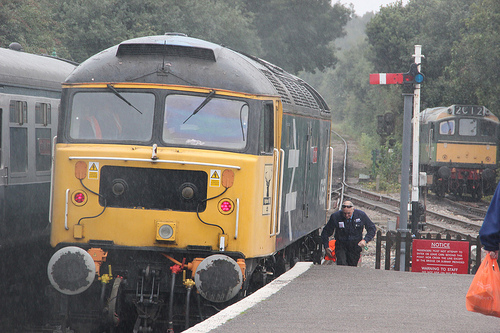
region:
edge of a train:
[259, 169, 271, 220]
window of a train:
[192, 120, 202, 133]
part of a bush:
[454, 51, 459, 62]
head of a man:
[343, 193, 351, 213]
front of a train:
[117, 250, 139, 270]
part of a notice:
[416, 243, 427, 253]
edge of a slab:
[275, 281, 277, 286]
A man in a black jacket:
[318, 200, 378, 265]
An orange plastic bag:
[463, 255, 495, 316]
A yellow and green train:
[416, 105, 499, 196]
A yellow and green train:
[47, 30, 330, 330]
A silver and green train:
[0, 40, 77, 310]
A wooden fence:
[374, 229, 486, 276]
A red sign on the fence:
[413, 238, 469, 274]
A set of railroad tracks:
[328, 128, 488, 246]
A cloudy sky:
[326, 0, 413, 17]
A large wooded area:
[1, 0, 498, 147]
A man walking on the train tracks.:
[321, 191, 371, 259]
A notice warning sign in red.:
[409, 234, 470, 271]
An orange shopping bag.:
[464, 248, 499, 314]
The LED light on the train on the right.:
[215, 195, 235, 217]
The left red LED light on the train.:
[72, 189, 86, 205]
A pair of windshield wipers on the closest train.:
[102, 81, 219, 124]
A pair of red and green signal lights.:
[405, 65, 423, 85]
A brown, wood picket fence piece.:
[370, 228, 482, 269]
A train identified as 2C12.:
[417, 101, 493, 194]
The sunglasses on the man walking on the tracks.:
[338, 200, 355, 211]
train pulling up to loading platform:
[45, 31, 335, 330]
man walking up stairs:
[318, 198, 376, 268]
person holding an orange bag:
[464, 178, 499, 320]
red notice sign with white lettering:
[408, 235, 470, 275]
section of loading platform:
[181, 263, 498, 332]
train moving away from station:
[411, 103, 498, 201]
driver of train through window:
[76, 97, 123, 142]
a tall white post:
[408, 43, 425, 205]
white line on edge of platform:
[183, 258, 314, 331]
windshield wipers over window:
[105, 82, 216, 124]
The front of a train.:
[27, 29, 287, 319]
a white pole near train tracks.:
[353, 28, 440, 234]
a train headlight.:
[155, 218, 183, 247]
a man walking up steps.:
[311, 184, 383, 279]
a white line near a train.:
[177, 247, 322, 332]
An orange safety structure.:
[459, 237, 498, 320]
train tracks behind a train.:
[318, 180, 485, 255]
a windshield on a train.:
[160, 80, 255, 154]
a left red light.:
[212, 193, 232, 223]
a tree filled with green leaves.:
[361, 0, 498, 131]